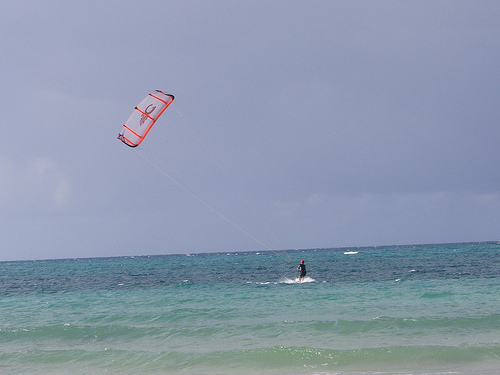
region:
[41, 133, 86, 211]
this is the sky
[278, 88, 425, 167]
the sky is blue in color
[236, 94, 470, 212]
the sky is clear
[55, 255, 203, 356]
this is an ocean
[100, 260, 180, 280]
this is the ocean water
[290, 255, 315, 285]
this is a man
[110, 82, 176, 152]
this is a kite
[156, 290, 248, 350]
the water is wavy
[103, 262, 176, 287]
the water is blue in color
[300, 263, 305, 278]
the swimsuit is black in color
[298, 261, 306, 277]
Man standing in water.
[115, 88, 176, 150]
Kite flying in the air over the ocean.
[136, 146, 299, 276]
String attached to kite being held by man.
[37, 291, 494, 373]
Ocean is green with waves.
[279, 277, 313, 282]
Ocean is white and is foaming.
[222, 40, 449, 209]
Blue cloudless sky.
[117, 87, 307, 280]
Man flying kite in the ocean.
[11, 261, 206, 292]
Ocean dark blue with waves.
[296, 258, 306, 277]
Man dressed in black in the water.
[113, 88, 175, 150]
Kite colored gray and orange.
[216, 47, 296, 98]
this is the sky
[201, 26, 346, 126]
the sky is blue in color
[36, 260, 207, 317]
the ocean is blue in color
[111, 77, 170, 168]
this is a kite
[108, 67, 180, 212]
the kite is grey and orange in color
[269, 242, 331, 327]
this is a person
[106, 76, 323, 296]
the man is fyling a kite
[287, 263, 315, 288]
the clothes of the man is black in color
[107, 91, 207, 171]
the kite is flying high in the sky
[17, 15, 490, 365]
Picture taken at the ocean.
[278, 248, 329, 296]
Person in the water kite surfing.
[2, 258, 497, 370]
The water is blue and green.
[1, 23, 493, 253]
The sky is grey and hazy.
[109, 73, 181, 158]
Large kite for surfing.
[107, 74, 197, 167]
The kit is white with red stripes and lettering.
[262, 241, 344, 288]
One person in the photo.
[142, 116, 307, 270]
Kite strings.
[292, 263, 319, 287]
Black wet suit.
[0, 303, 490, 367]
Waves in the water.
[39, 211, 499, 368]
the ocean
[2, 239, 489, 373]
the ocean water is blue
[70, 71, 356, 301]
a person is windsurfing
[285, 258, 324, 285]
a person on the water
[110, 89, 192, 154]
a parachute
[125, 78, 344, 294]
a person holding a rope to a parachute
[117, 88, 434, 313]
windsurfing in the ocean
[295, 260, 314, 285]
the person is wearing a wetsuit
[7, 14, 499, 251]
a cloudy day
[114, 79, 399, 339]
a person being pulled by the wind